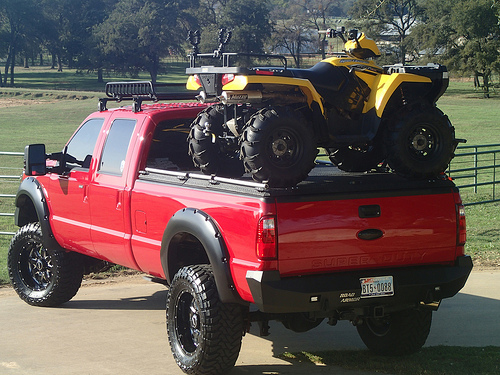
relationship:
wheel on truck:
[7, 219, 88, 309] [10, 77, 476, 373]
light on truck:
[255, 213, 277, 257] [33, 105, 438, 318]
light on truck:
[456, 203, 470, 246] [33, 105, 438, 318]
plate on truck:
[357, 275, 396, 297] [10, 77, 476, 373]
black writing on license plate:
[359, 281, 394, 292] [361, 269, 404, 301]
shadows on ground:
[102, 290, 487, 360] [5, 269, 495, 370]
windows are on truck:
[59, 114, 101, 178] [26, 49, 459, 373]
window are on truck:
[95, 116, 137, 178] [26, 49, 459, 373]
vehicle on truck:
[189, 28, 444, 178] [10, 77, 476, 373]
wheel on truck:
[163, 264, 246, 374] [10, 77, 476, 373]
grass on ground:
[5, 100, 77, 128] [8, 77, 493, 272]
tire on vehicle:
[229, 95, 323, 196] [184, 28, 465, 191]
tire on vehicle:
[362, 91, 469, 180] [184, 28, 465, 191]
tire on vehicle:
[184, 96, 247, 181] [173, 19, 473, 189]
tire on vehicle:
[319, 141, 383, 177] [184, 28, 465, 191]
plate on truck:
[357, 275, 396, 300] [1, 79, 450, 364]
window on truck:
[103, 114, 137, 178] [1, 79, 450, 364]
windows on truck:
[59, 116, 105, 174] [7, 80, 476, 375]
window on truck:
[95, 116, 137, 178] [7, 80, 476, 375]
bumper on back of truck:
[246, 255, 473, 315] [10, 77, 476, 373]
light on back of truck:
[262, 218, 276, 229] [29, 135, 281, 275]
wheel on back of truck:
[163, 257, 236, 373] [10, 77, 476, 373]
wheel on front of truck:
[3, 223, 90, 311] [3, 24, 476, 369]